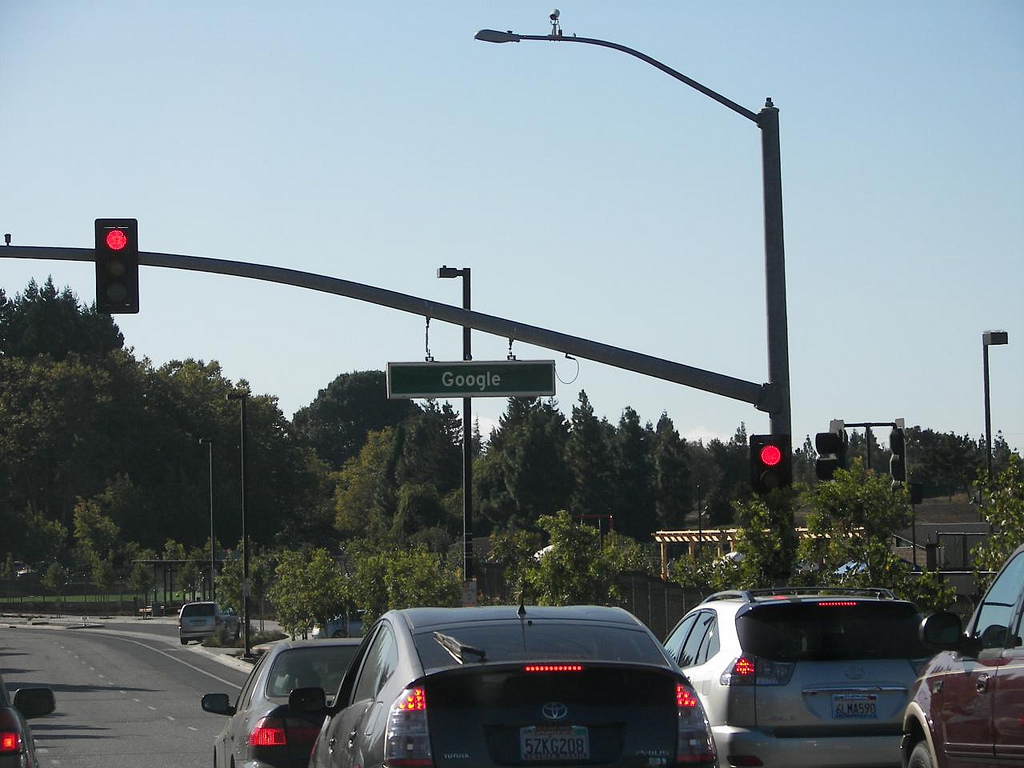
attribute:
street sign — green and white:
[380, 351, 560, 401]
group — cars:
[198, 577, 989, 765]